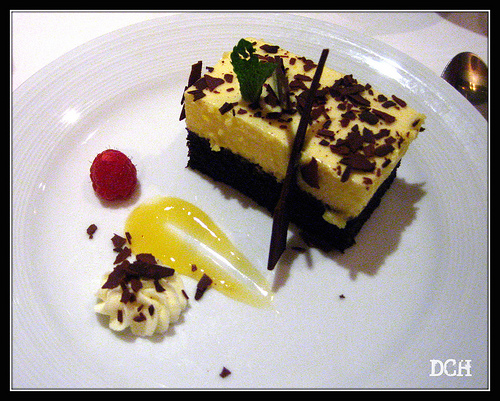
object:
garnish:
[231, 36, 279, 106]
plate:
[11, 10, 498, 399]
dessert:
[81, 29, 427, 340]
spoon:
[443, 48, 488, 116]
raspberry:
[88, 147, 140, 202]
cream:
[93, 259, 192, 342]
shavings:
[101, 251, 178, 299]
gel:
[125, 196, 269, 319]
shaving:
[263, 48, 329, 277]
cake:
[178, 34, 427, 270]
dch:
[427, 353, 475, 381]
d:
[427, 355, 444, 384]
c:
[443, 356, 457, 380]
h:
[457, 356, 475, 381]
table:
[13, 10, 494, 90]